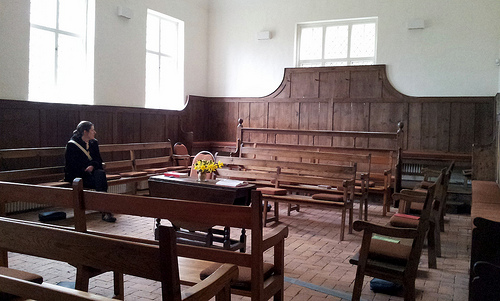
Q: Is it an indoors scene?
A: Yes, it is indoors.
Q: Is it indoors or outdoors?
A: It is indoors.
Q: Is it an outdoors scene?
A: No, it is indoors.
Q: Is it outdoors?
A: No, it is indoors.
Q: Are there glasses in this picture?
A: No, there are no glasses.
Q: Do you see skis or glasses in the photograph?
A: No, there are no glasses or skis.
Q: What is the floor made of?
A: The floor is made of brick.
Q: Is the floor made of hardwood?
A: No, the floor is made of brick.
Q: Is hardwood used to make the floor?
A: No, the floor is made of brick.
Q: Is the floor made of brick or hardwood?
A: The floor is made of brick.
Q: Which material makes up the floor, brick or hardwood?
A: The floor is made of brick.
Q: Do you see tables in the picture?
A: Yes, there is a table.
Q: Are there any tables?
A: Yes, there is a table.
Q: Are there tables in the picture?
A: Yes, there is a table.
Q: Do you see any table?
A: Yes, there is a table.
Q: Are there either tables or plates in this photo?
A: Yes, there is a table.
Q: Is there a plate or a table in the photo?
A: Yes, there is a table.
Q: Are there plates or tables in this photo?
A: Yes, there is a table.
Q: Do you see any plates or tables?
A: Yes, there is a table.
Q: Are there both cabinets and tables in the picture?
A: No, there is a table but no cabinets.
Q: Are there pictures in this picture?
A: No, there are no pictures.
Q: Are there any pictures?
A: No, there are no pictures.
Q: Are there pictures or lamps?
A: No, there are no pictures or lamps.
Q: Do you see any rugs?
A: No, there are no rugs.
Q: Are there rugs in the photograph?
A: No, there are no rugs.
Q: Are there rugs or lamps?
A: No, there are no rugs or lamps.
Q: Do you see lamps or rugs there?
A: No, there are no rugs or lamps.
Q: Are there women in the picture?
A: Yes, there is a woman.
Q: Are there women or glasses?
A: Yes, there is a woman.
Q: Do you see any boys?
A: No, there are no boys.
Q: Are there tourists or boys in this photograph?
A: No, there are no boys or tourists.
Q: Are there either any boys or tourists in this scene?
A: No, there are no boys or tourists.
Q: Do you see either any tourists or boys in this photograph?
A: No, there are no boys or tourists.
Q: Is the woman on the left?
A: Yes, the woman is on the left of the image.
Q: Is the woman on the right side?
A: No, the woman is on the left of the image.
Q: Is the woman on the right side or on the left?
A: The woman is on the left of the image.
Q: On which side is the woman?
A: The woman is on the left of the image.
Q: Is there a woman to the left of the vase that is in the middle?
A: Yes, there is a woman to the left of the vase.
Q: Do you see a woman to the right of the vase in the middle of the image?
A: No, the woman is to the left of the vase.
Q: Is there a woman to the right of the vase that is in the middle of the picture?
A: No, the woman is to the left of the vase.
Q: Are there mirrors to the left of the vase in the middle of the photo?
A: No, there is a woman to the left of the vase.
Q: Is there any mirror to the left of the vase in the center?
A: No, there is a woman to the left of the vase.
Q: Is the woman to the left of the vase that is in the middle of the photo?
A: Yes, the woman is to the left of the vase.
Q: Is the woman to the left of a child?
A: No, the woman is to the left of the vase.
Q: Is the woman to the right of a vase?
A: No, the woman is to the left of a vase.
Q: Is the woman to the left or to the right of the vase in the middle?
A: The woman is to the left of the vase.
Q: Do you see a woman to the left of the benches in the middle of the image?
A: Yes, there is a woman to the left of the benches.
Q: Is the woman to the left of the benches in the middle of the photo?
A: Yes, the woman is to the left of the benches.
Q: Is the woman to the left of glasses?
A: No, the woman is to the left of the benches.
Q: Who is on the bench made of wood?
A: The woman is on the bench.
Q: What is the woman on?
A: The woman is on the bench.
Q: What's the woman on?
A: The woman is on the bench.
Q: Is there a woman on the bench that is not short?
A: Yes, there is a woman on the bench.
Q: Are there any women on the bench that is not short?
A: Yes, there is a woman on the bench.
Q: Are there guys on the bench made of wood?
A: No, there is a woman on the bench.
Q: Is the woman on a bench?
A: Yes, the woman is on a bench.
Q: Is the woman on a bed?
A: No, the woman is on a bench.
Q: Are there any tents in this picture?
A: No, there are no tents.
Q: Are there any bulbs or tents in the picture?
A: No, there are no tents or bulbs.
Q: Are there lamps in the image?
A: No, there are no lamps.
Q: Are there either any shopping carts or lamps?
A: No, there are no lamps or shopping carts.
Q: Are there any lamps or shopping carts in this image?
A: No, there are no lamps or shopping carts.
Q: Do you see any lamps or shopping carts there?
A: No, there are no lamps or shopping carts.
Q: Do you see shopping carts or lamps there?
A: No, there are no lamps or shopping carts.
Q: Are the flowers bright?
A: Yes, the flowers are bright.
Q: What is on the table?
A: The flowers are on the table.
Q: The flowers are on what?
A: The flowers are on the table.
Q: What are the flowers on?
A: The flowers are on the table.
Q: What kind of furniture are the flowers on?
A: The flowers are on the table.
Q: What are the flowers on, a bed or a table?
A: The flowers are on a table.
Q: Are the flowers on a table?
A: Yes, the flowers are on a table.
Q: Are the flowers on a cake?
A: No, the flowers are on a table.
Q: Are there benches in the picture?
A: Yes, there is a bench.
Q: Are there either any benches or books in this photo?
A: Yes, there is a bench.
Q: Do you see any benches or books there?
A: Yes, there is a bench.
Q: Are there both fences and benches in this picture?
A: No, there is a bench but no fences.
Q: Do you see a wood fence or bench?
A: Yes, there is a wood bench.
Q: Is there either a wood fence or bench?
A: Yes, there is a wood bench.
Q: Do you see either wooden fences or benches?
A: Yes, there is a wood bench.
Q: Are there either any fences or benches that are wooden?
A: Yes, the bench is wooden.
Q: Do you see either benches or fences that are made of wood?
A: Yes, the bench is made of wood.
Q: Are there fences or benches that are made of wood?
A: Yes, the bench is made of wood.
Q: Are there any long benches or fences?
A: Yes, there is a long bench.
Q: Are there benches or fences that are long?
A: Yes, the bench is long.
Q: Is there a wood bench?
A: Yes, there is a bench that is made of wood.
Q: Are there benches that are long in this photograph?
A: Yes, there is a long bench.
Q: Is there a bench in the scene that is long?
A: Yes, there is a bench that is long.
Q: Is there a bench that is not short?
A: Yes, there is a long bench.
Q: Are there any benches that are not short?
A: Yes, there is a long bench.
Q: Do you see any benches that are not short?
A: Yes, there is a long bench.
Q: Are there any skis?
A: No, there are no skis.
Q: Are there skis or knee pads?
A: No, there are no skis or knee pads.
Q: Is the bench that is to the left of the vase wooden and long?
A: Yes, the bench is wooden and long.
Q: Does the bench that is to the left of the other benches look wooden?
A: Yes, the bench is wooden.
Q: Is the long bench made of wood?
A: Yes, the bench is made of wood.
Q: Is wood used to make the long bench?
A: Yes, the bench is made of wood.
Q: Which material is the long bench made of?
A: The bench is made of wood.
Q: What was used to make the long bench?
A: The bench is made of wood.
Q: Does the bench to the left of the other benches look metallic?
A: No, the bench is wooden.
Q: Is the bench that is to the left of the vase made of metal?
A: No, the bench is made of wood.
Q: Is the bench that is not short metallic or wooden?
A: The bench is wooden.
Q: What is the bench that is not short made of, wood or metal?
A: The bench is made of wood.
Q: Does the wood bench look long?
A: Yes, the bench is long.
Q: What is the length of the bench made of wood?
A: The bench is long.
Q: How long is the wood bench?
A: The bench is long.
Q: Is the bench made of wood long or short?
A: The bench is long.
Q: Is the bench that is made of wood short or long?
A: The bench is long.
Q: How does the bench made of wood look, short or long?
A: The bench is long.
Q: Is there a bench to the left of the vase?
A: Yes, there is a bench to the left of the vase.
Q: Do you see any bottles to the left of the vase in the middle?
A: No, there is a bench to the left of the vase.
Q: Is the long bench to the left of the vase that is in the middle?
A: Yes, the bench is to the left of the vase.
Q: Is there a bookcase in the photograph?
A: No, there are no bookcases.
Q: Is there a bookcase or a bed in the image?
A: No, there are no bookcases or beds.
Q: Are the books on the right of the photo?
A: Yes, the books are on the right of the image.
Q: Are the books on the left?
A: No, the books are on the right of the image.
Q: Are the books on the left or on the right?
A: The books are on the right of the image.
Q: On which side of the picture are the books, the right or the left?
A: The books are on the right of the image.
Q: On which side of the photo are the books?
A: The books are on the right of the image.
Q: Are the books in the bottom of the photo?
A: Yes, the books are in the bottom of the image.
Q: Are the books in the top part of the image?
A: No, the books are in the bottom of the image.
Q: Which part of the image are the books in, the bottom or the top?
A: The books are in the bottom of the image.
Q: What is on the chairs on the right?
A: The books are on the chairs.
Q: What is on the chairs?
A: The books are on the chairs.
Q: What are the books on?
A: The books are on the chairs.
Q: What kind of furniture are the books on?
A: The books are on the chairs.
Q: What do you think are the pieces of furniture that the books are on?
A: The pieces of furniture are chairs.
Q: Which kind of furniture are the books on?
A: The books are on the chairs.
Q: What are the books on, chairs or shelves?
A: The books are on chairs.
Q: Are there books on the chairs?
A: Yes, there are books on the chairs.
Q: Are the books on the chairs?
A: Yes, the books are on the chairs.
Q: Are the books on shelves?
A: No, the books are on the chairs.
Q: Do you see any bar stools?
A: No, there are no bar stools.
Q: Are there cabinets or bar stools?
A: No, there are no bar stools or cabinets.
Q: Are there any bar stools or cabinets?
A: No, there are no bar stools or cabinets.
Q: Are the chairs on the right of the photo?
A: Yes, the chairs are on the right of the image.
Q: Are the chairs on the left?
A: No, the chairs are on the right of the image.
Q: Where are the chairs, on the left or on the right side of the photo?
A: The chairs are on the right of the image.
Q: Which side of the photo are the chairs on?
A: The chairs are on the right of the image.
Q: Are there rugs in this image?
A: No, there are no rugs.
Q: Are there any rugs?
A: No, there are no rugs.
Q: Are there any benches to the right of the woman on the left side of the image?
A: Yes, there are benches to the right of the woman.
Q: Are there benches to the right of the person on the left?
A: Yes, there are benches to the right of the woman.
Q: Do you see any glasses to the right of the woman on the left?
A: No, there are benches to the right of the woman.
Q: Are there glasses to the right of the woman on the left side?
A: No, there are benches to the right of the woman.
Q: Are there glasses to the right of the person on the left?
A: No, there are benches to the right of the woman.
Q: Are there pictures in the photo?
A: No, there are no pictures.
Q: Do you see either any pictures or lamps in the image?
A: No, there are no pictures or lamps.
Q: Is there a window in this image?
A: Yes, there is a window.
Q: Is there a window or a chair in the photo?
A: Yes, there is a window.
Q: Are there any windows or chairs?
A: Yes, there is a window.